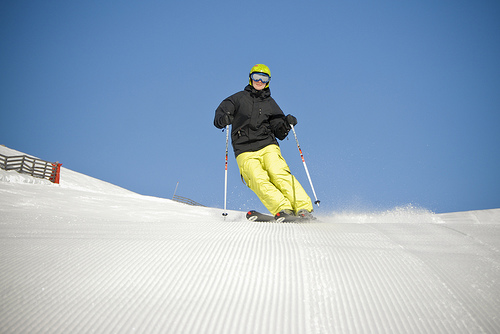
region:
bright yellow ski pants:
[232, 144, 315, 214]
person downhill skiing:
[200, 63, 323, 223]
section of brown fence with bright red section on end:
[0, 149, 62, 191]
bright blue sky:
[0, 8, 497, 208]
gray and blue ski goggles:
[250, 70, 269, 85]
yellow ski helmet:
[248, 59, 271, 89]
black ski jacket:
[208, 81, 297, 156]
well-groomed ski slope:
[1, 138, 498, 332]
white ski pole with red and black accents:
[221, 110, 233, 226]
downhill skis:
[242, 202, 325, 224]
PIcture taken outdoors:
[61, 31, 446, 323]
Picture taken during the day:
[26, 11, 369, 331]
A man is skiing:
[207, 70, 310, 241]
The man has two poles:
[211, 107, 338, 222]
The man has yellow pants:
[239, 156, 313, 212]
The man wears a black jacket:
[209, 91, 290, 147]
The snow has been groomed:
[109, 199, 419, 309]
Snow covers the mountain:
[65, 178, 438, 303]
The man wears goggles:
[250, 69, 270, 81]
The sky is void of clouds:
[343, 66, 433, 157]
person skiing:
[198, 55, 369, 260]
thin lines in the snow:
[35, 223, 458, 330]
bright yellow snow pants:
[232, 141, 310, 210]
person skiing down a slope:
[1, 56, 497, 333]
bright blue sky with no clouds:
[1, 2, 499, 220]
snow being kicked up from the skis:
[317, 205, 437, 223]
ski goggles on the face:
[250, 71, 274, 81]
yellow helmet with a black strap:
[244, 61, 279, 95]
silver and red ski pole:
[286, 120, 329, 210]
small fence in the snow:
[1, 139, 73, 190]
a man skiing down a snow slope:
[190, 42, 382, 297]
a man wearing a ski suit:
[192, 50, 329, 249]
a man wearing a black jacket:
[197, 54, 311, 161]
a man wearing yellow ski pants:
[211, 50, 329, 239]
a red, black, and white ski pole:
[216, 118, 236, 223]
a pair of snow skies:
[236, 200, 319, 237]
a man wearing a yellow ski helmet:
[242, 58, 275, 101]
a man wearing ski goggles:
[243, 56, 277, 97]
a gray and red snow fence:
[0, 145, 70, 186]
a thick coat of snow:
[27, 230, 457, 325]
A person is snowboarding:
[162, 48, 337, 235]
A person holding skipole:
[219, 125, 232, 223]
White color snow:
[106, 207, 179, 294]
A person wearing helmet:
[248, 58, 273, 73]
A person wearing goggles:
[248, 72, 274, 84]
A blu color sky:
[86, 34, 141, 106]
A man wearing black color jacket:
[212, 90, 309, 143]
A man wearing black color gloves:
[223, 109, 295, 132]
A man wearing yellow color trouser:
[241, 156, 311, 209]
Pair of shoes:
[276, 208, 316, 228]